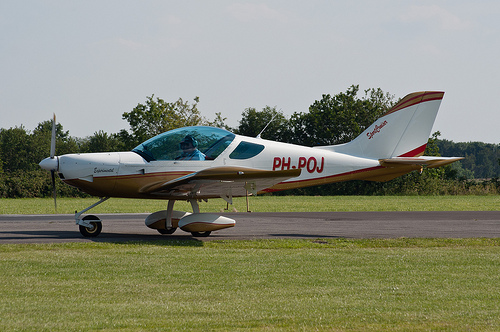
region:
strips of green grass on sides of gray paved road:
[6, 192, 492, 327]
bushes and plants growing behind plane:
[0, 82, 495, 187]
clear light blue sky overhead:
[2, 6, 492, 141]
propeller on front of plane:
[35, 120, 65, 211]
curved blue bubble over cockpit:
[131, 120, 231, 161]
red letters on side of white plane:
[267, 140, 323, 175]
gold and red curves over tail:
[380, 80, 445, 122]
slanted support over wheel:
[52, 197, 112, 237]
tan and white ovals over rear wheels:
[140, 200, 237, 240]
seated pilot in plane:
[165, 131, 206, 168]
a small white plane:
[30, 85, 465, 243]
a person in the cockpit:
[175, 130, 206, 161]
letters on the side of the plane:
[269, 149, 327, 178]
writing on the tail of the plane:
[364, 110, 389, 141]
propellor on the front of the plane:
[31, 110, 69, 215]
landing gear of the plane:
[65, 188, 239, 242]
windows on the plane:
[127, 120, 265, 166]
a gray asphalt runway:
[0, 207, 499, 242]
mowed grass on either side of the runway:
[2, 191, 497, 330]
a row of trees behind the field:
[0, 85, 498, 192]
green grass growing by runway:
[23, 244, 427, 328]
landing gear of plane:
[65, 206, 102, 233]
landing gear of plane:
[185, 210, 222, 237]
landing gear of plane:
[146, 206, 178, 228]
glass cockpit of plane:
[143, 125, 224, 159]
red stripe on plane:
[309, 157, 381, 182]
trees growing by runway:
[18, 106, 484, 196]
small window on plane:
[233, 134, 280, 159]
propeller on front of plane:
[46, 115, 59, 195]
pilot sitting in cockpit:
[178, 130, 200, 166]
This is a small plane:
[28, 89, 467, 244]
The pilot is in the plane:
[171, 113, 215, 170]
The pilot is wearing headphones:
[177, 125, 208, 166]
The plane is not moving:
[26, 101, 465, 226]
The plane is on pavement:
[0, 193, 468, 240]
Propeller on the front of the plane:
[31, 108, 72, 215]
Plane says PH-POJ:
[260, 146, 347, 178]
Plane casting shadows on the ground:
[23, 219, 188, 244]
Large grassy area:
[3, 243, 492, 329]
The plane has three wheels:
[61, 194, 238, 239]